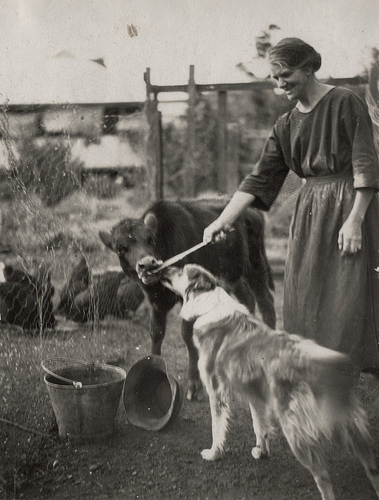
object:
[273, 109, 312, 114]
wall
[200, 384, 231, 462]
leg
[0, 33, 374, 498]
farm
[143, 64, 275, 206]
wooden chicken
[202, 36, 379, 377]
woman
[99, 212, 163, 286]
head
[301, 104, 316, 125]
ground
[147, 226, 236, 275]
spoon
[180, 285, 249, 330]
dress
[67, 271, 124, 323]
chicken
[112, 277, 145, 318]
chicken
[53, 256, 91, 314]
chicken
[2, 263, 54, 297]
chicken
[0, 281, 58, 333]
chicken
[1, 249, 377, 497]
ground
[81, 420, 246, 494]
yard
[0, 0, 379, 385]
fence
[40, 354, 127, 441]
bucket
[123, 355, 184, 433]
hat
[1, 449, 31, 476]
ground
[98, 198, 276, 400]
calf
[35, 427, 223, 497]
ground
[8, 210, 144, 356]
coop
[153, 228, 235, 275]
stick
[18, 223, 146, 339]
chicken wire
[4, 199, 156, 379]
yard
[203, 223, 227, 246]
hand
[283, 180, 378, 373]
dress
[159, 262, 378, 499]
animals